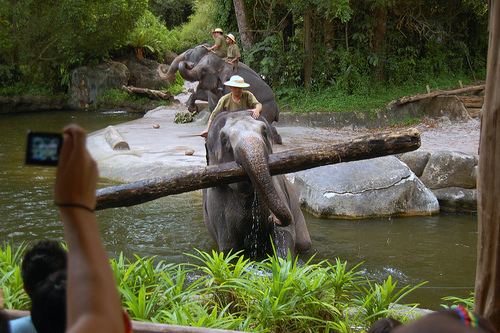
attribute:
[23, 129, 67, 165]
camera — recording, taking picture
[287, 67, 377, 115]
grass — green, tufts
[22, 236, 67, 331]
hair — brown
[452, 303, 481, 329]
ribbon — colorful, small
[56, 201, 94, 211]
strap — black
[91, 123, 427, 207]
log — large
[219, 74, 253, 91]
hat — safari hat, straw, brown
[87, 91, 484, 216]
rock — flat, large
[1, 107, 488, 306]
water — green, murky, small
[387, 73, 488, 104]
tree — fallen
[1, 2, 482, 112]
vegetation — forest, green, dense, lush, jungle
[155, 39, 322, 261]
elephants — gray, large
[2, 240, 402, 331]
plants — green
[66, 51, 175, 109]
boulders — large, gray, giant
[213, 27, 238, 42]
hats — straw